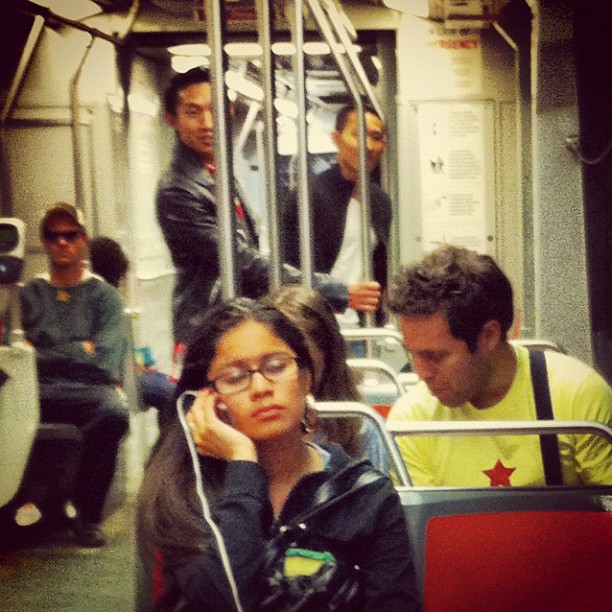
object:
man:
[153, 65, 381, 346]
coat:
[281, 163, 392, 327]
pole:
[292, 0, 313, 285]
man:
[2, 202, 127, 547]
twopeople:
[138, 281, 416, 612]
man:
[380, 240, 612, 485]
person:
[260, 283, 387, 477]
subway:
[0, 0, 612, 612]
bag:
[527, 344, 565, 486]